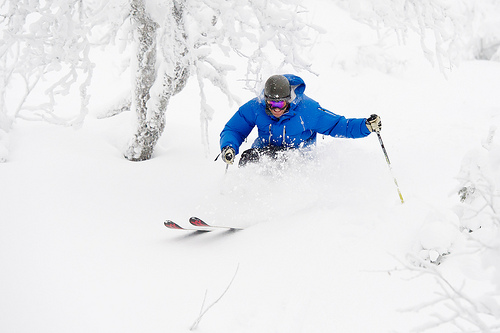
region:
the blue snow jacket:
[196, 75, 378, 152]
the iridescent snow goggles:
[263, 96, 292, 111]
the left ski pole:
[363, 108, 425, 231]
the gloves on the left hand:
[363, 109, 388, 140]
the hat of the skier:
[261, 73, 297, 95]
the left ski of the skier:
[190, 218, 249, 230]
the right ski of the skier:
[160, 216, 204, 238]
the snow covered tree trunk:
[126, 3, 202, 175]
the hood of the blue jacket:
[283, 71, 311, 101]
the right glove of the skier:
[221, 145, 243, 166]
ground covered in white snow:
[31, 204, 141, 296]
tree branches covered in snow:
[397, 246, 492, 332]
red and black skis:
[149, 211, 252, 239]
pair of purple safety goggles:
[258, 93, 293, 113]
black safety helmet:
[256, 72, 300, 104]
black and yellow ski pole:
[362, 121, 417, 222]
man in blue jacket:
[208, 65, 390, 177]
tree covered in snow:
[104, 0, 216, 157]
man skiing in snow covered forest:
[112, 3, 419, 248]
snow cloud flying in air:
[240, 156, 326, 215]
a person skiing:
[127, 22, 429, 269]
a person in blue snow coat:
[114, 10, 442, 279]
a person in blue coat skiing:
[146, 45, 403, 276]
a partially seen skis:
[151, 181, 282, 256]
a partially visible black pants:
[237, 142, 310, 186]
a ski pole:
[359, 110, 416, 228]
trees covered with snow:
[27, 7, 186, 183]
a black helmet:
[251, 65, 299, 102]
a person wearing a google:
[260, 73, 305, 121]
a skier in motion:
[123, 33, 427, 283]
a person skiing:
[139, 61, 424, 274]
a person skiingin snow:
[138, 58, 489, 298]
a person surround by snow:
[135, 40, 458, 234]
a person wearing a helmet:
[175, 40, 387, 207]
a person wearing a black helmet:
[217, 71, 416, 209]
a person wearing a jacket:
[202, 59, 413, 231]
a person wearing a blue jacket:
[149, 31, 399, 186]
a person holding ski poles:
[183, 32, 413, 251]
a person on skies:
[134, 31, 369, 243]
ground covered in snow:
[36, 208, 182, 330]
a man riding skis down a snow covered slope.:
[140, 68, 417, 251]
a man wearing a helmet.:
[254, 73, 312, 118]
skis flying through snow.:
[147, 188, 299, 243]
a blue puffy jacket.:
[209, 84, 380, 155]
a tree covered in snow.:
[104, 1, 204, 186]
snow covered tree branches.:
[3, 0, 112, 140]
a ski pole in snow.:
[358, 106, 417, 218]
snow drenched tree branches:
[397, 121, 497, 329]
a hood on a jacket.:
[275, 68, 323, 114]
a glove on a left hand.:
[216, 143, 250, 168]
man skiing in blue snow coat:
[160, 70, 407, 237]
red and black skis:
[147, 196, 258, 250]